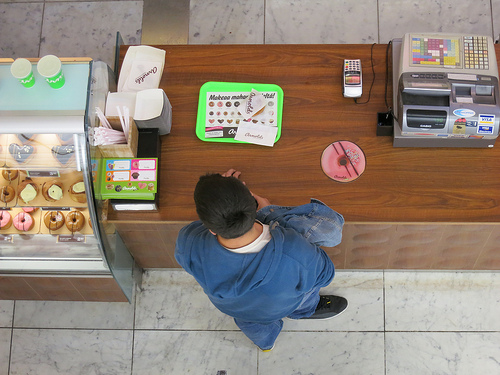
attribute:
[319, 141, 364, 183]
cd — red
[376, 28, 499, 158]
cash register — gray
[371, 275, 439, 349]
floor — tiled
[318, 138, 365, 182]
donut — large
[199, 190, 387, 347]
man — in blue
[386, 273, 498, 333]
tile — white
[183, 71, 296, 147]
mat — green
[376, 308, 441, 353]
floor — part of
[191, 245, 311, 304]
hood — blue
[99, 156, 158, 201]
box — green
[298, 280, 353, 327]
shoe — part of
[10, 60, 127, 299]
display case — glass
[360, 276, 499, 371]
tiles — white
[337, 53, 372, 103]
card reader — black, silver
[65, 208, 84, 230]
donut — brown, frosted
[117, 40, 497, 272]
table — part of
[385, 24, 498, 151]
register — cash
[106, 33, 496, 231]
counter — brown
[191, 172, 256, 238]
hair — black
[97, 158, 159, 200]
flyers — promotional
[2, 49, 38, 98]
small cup — green, paper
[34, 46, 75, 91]
large cup — paper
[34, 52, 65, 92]
cup — green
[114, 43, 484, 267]
counter — wooden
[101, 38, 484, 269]
checkout counter — wooden